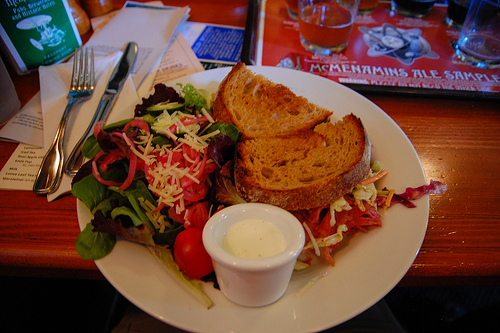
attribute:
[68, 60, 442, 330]
plate — white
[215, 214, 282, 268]
sauce — white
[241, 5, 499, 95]
tray — white, red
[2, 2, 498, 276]
table — wooden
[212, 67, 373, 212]
sandwich bread — toasted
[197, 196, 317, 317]
container — small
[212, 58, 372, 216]
bread — toasted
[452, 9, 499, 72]
glass — empty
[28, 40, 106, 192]
fork — stainless steel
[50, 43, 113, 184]
fork — silver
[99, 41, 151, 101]
knife — silver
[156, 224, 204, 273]
tomato — red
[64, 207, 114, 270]
lettuce — green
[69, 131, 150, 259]
salad — green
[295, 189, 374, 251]
meat — grilled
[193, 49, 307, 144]
bread — toasted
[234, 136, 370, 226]
bread — toasted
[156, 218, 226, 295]
tomato — red, small